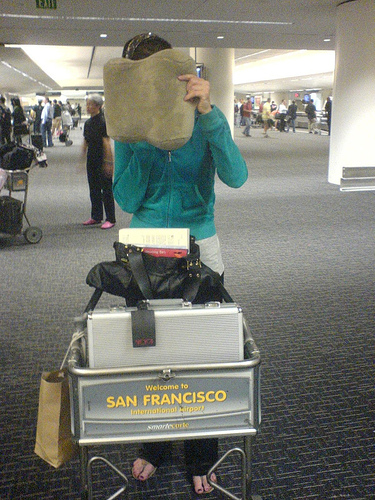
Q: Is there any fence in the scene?
A: No, there are no fences.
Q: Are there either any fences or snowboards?
A: No, there are no fences or snowboards.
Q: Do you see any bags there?
A: Yes, there is a bag.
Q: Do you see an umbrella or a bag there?
A: Yes, there is a bag.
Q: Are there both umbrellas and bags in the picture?
A: No, there is a bag but no umbrellas.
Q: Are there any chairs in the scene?
A: No, there are no chairs.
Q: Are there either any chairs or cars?
A: No, there are no chairs or cars.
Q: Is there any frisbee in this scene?
A: No, there are no frisbees.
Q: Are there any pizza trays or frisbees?
A: No, there are no frisbees or pizza trays.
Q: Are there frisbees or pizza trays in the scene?
A: No, there are no frisbees or pizza trays.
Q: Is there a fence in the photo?
A: No, there are no fences.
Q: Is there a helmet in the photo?
A: No, there are no helmets.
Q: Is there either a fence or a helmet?
A: No, there are no helmets or fences.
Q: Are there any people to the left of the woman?
A: Yes, there is a person to the left of the woman.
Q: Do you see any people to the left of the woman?
A: Yes, there is a person to the left of the woman.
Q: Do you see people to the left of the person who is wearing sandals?
A: Yes, there is a person to the left of the woman.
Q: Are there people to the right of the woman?
A: No, the person is to the left of the woman.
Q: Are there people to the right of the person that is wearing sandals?
A: No, the person is to the left of the woman.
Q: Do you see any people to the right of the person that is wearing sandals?
A: No, the person is to the left of the woman.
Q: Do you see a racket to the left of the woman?
A: No, there is a person to the left of the woman.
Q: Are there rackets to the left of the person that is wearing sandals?
A: No, there is a person to the left of the woman.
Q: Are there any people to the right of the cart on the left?
A: Yes, there is a person to the right of the cart.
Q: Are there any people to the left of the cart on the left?
A: No, the person is to the right of the cart.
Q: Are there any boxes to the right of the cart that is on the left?
A: No, there is a person to the right of the cart.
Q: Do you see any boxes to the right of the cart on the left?
A: No, there is a person to the right of the cart.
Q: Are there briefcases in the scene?
A: Yes, there is a briefcase.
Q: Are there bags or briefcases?
A: Yes, there is a briefcase.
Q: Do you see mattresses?
A: No, there are no mattresses.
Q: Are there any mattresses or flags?
A: No, there are no mattresses or flags.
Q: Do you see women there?
A: Yes, there is a woman.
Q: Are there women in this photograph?
A: Yes, there is a woman.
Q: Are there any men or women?
A: Yes, there is a woman.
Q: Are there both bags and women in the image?
A: Yes, there are both a woman and a bag.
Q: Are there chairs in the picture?
A: No, there are no chairs.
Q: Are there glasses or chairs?
A: No, there are no chairs or glasses.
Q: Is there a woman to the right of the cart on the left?
A: Yes, there is a woman to the right of the cart.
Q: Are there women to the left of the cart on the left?
A: No, the woman is to the right of the cart.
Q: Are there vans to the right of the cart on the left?
A: No, there is a woman to the right of the cart.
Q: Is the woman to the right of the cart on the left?
A: Yes, the woman is to the right of the cart.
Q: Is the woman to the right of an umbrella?
A: No, the woman is to the right of the cart.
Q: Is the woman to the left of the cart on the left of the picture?
A: No, the woman is to the right of the cart.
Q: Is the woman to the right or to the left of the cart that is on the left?
A: The woman is to the right of the cart.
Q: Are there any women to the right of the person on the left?
A: Yes, there is a woman to the right of the person.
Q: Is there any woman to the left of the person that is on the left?
A: No, the woman is to the right of the person.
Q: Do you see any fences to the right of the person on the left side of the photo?
A: No, there is a woman to the right of the person.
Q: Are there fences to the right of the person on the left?
A: No, there is a woman to the right of the person.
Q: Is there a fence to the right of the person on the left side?
A: No, there is a woman to the right of the person.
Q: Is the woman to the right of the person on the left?
A: Yes, the woman is to the right of the person.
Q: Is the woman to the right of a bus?
A: No, the woman is to the right of the person.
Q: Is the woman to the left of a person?
A: No, the woman is to the right of a person.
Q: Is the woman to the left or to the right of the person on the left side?
A: The woman is to the right of the person.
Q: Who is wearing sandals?
A: The woman is wearing sandals.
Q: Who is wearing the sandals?
A: The woman is wearing sandals.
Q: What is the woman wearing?
A: The woman is wearing sandals.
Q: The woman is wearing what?
A: The woman is wearing sandals.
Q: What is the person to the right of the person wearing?
A: The woman is wearing sandals.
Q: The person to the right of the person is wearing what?
A: The woman is wearing sandals.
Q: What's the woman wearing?
A: The woman is wearing sandals.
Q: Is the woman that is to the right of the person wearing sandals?
A: Yes, the woman is wearing sandals.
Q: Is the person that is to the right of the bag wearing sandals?
A: Yes, the woman is wearing sandals.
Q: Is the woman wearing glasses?
A: No, the woman is wearing sandals.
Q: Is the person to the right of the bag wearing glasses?
A: No, the woman is wearing sandals.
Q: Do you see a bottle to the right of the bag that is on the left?
A: No, there is a woman to the right of the bag.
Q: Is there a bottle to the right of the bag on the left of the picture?
A: No, there is a woman to the right of the bag.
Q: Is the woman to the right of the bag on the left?
A: Yes, the woman is to the right of the bag.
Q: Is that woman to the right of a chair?
A: No, the woman is to the right of the bag.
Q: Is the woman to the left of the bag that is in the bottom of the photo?
A: No, the woman is to the right of the bag.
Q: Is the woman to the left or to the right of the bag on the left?
A: The woman is to the right of the bag.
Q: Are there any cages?
A: No, there are no cages.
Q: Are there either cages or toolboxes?
A: No, there are no cages or toolboxes.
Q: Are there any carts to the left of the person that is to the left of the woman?
A: Yes, there is a cart to the left of the person.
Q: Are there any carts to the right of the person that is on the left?
A: No, the cart is to the left of the person.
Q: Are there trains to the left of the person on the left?
A: No, there is a cart to the left of the person.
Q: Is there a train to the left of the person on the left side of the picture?
A: No, there is a cart to the left of the person.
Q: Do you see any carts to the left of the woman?
A: Yes, there is a cart to the left of the woman.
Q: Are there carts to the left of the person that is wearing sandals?
A: Yes, there is a cart to the left of the woman.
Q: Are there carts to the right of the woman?
A: No, the cart is to the left of the woman.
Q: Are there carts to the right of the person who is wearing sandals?
A: No, the cart is to the left of the woman.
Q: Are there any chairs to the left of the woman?
A: No, there is a cart to the left of the woman.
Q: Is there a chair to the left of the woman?
A: No, there is a cart to the left of the woman.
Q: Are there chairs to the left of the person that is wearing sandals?
A: No, there is a cart to the left of the woman.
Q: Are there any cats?
A: No, there are no cats.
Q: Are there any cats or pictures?
A: No, there are no cats or pictures.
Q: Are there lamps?
A: No, there are no lamps.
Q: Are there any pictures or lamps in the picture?
A: No, there are no lamps or pictures.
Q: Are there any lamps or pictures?
A: No, there are no lamps or pictures.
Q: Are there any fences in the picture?
A: No, there are no fences.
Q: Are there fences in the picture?
A: No, there are no fences.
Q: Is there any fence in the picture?
A: No, there are no fences.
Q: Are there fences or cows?
A: No, there are no fences or cows.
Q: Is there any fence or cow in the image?
A: No, there are no fences or cows.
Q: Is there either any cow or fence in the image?
A: No, there are no fences or cows.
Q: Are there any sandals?
A: Yes, there are sandals.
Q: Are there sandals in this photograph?
A: Yes, there are sandals.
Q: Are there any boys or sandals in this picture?
A: Yes, there are sandals.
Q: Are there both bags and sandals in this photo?
A: Yes, there are both sandals and a bag.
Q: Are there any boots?
A: No, there are no boots.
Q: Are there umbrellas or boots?
A: No, there are no boots or umbrellas.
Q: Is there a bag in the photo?
A: Yes, there is a bag.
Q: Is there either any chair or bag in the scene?
A: Yes, there is a bag.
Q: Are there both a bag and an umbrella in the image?
A: No, there is a bag but no umbrellas.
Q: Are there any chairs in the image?
A: No, there are no chairs.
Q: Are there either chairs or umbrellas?
A: No, there are no chairs or umbrellas.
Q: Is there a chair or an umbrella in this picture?
A: No, there are no chairs or umbrellas.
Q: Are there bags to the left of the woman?
A: Yes, there is a bag to the left of the woman.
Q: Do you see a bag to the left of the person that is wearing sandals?
A: Yes, there is a bag to the left of the woman.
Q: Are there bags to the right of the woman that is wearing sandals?
A: No, the bag is to the left of the woman.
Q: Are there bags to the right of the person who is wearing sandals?
A: No, the bag is to the left of the woman.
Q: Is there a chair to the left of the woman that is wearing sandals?
A: No, there is a bag to the left of the woman.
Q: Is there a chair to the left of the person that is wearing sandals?
A: No, there is a bag to the left of the woman.